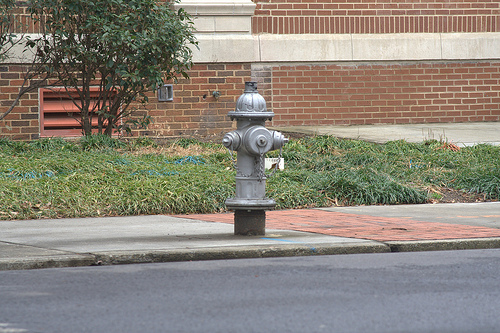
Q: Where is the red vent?
A: Side of building.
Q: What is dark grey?
A: The street.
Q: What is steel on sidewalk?
A: Hydrant.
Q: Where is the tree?
A: Near building.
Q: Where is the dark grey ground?
A: In front of hydrant.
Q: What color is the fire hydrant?
A: Silver.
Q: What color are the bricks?
A: Red.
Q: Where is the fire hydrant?
A: On the sidewalk.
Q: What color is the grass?
A: Green.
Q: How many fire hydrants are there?
A: One.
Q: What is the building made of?
A: Brick.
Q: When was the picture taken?
A: Daytime.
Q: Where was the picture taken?
A: Near hydrant.